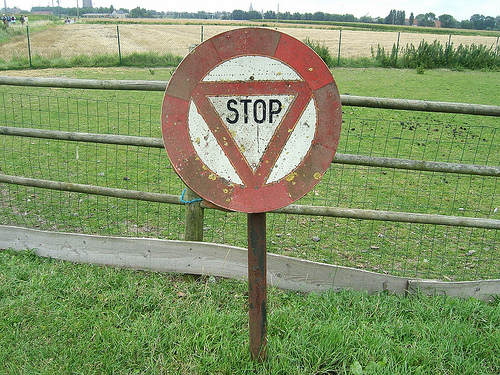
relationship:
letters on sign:
[214, 86, 272, 132] [152, 22, 363, 230]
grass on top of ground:
[375, 74, 423, 93] [102, 17, 152, 48]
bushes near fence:
[373, 41, 474, 70] [15, 75, 126, 207]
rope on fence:
[166, 185, 194, 209] [15, 75, 126, 207]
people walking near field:
[1, 6, 70, 32] [70, 29, 130, 50]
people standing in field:
[1, 6, 70, 32] [70, 29, 130, 50]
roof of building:
[26, 8, 56, 18] [28, 9, 64, 23]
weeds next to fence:
[75, 44, 135, 62] [15, 75, 126, 207]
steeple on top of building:
[84, 0, 92, 3] [28, 9, 64, 23]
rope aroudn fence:
[166, 185, 194, 209] [15, 75, 126, 207]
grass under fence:
[375, 74, 423, 93] [15, 75, 126, 207]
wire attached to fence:
[64, 92, 137, 197] [15, 75, 126, 207]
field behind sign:
[70, 29, 130, 50] [152, 22, 363, 230]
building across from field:
[28, 9, 64, 23] [70, 29, 130, 50]